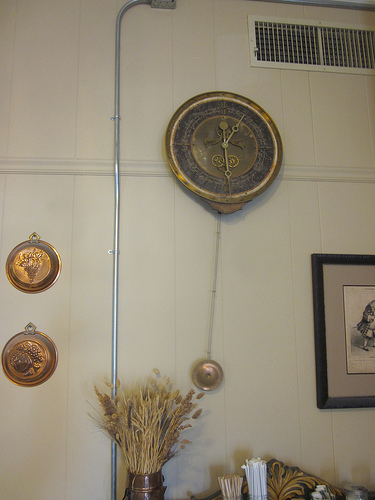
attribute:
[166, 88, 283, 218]
clock — gold, antique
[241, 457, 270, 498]
straws — White 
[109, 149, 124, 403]
pole — silver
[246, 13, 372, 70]
vent — white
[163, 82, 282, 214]
clock — old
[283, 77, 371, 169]
wall — antique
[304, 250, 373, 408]
picture — framed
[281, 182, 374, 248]
wall — framed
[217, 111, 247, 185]
arms — gold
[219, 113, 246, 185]
arms — fancy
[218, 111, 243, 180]
arms — fancy, gold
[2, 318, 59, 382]
pot — copper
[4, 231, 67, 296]
pot — gold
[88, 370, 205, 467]
wheat plant — tan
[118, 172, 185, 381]
paneling — white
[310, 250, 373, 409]
art — black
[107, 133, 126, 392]
pole — silver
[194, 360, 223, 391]
bell — gold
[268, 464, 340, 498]
sculpture — gold, black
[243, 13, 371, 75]
vent — metal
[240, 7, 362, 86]
vent — white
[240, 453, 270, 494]
wrappers — white, straw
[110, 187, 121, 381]
pipe — thin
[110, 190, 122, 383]
pipe — silver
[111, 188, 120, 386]
pipe — metal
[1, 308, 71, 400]
bowl — golden